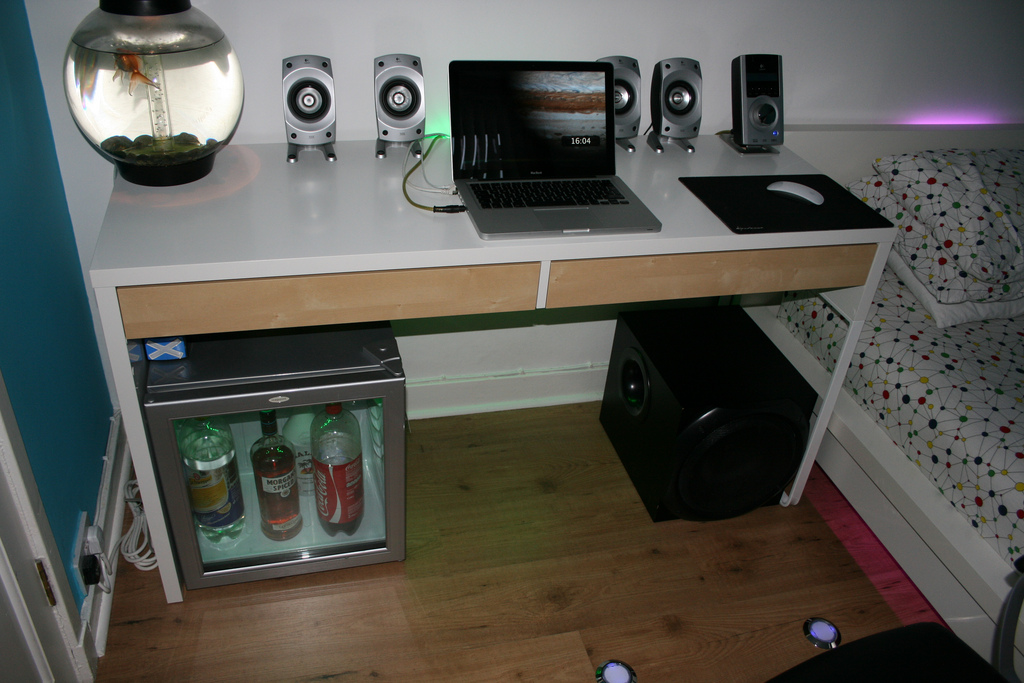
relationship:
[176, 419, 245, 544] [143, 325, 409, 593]
bottle in refrigerator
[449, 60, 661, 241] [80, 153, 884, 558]
laptop on desk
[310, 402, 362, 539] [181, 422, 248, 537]
coca cola in mini-fridge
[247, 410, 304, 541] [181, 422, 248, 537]
bottle in mini-fridge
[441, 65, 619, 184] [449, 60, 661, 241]
screen on laptop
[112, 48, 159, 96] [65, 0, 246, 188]
goldfish in aquarium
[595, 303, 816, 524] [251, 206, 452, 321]
sound system under desk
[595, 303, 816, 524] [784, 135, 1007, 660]
sound system next to bed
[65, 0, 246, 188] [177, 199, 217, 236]
aquarium on desk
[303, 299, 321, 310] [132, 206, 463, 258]
drawer in desk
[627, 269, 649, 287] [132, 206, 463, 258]
drawer in desk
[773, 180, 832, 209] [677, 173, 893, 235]
mouse on mouse pad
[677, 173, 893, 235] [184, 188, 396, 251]
mouse pad on desk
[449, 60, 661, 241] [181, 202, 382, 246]
laptop on desk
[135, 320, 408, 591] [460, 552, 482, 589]
fridge on floor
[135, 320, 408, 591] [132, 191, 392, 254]
fridge under desk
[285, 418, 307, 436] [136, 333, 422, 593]
bottle in fridge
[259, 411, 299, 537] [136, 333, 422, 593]
bottle in fridge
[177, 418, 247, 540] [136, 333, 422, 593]
bottle in fridge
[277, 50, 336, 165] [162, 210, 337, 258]
speaker on table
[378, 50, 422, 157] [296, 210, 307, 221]
speaker on table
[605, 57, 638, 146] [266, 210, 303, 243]
speaker on table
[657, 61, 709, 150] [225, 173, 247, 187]
speaker on table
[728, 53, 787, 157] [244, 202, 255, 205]
speaker on table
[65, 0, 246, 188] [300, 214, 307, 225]
aquarium on table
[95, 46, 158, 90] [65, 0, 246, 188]
goldfish in aquarium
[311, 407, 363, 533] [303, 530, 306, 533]
coca cola behind glass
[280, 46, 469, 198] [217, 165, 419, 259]
speakers on desk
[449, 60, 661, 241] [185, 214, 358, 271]
laptop on table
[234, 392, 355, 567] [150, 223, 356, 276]
chest under table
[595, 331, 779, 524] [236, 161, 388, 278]
sound system under table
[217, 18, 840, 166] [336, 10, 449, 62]
speaker system next to wall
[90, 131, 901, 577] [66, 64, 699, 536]
desk in room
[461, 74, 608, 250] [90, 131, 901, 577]
laptop on desk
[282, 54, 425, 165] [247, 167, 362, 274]
speakers on table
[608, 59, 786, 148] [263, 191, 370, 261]
speakers on table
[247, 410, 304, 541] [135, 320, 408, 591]
bottle in fridge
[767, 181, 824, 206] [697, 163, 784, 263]
mouse on mousepad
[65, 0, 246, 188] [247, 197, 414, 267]
aquarium on table